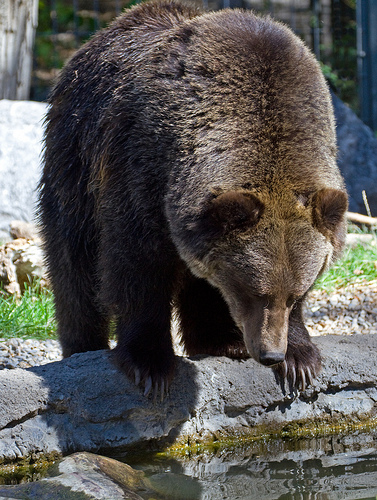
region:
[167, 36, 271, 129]
brown fur on a bear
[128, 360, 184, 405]
the claw of a bear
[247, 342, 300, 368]
the nose of a bear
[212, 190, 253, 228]
the ear of a bear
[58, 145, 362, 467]
a bear looking into the water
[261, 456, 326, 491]
reflection on the water's surface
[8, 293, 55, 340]
tall green grass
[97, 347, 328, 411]
a bear standing on rock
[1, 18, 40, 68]
the trunk of a tree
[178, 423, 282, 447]
moss on a rock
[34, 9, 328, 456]
Outdoor scene of a bear.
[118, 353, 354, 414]
The bear has long nails.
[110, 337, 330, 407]
The nails are brown.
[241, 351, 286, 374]
The bear's nose is black.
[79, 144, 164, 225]
The bear has brown fur.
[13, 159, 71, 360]
Picture taken during the day time.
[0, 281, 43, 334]
The grass is green.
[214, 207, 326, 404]
The bear is looking down at the water.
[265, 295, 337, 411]
The bear's left paw is off the rock.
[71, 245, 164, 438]
The bear's right front paw is on the rock.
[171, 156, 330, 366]
Grizzly Bears Fluffy Face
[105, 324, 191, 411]
Long grizzly bear claws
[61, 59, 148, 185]
Fluffy brown hair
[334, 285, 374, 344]
Rocks in the grass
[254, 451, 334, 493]
Clean drinking water for animals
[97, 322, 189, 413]
Dark colored long toe nails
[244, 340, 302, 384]
Black bear snout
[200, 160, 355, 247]
Two Grizzly Bear Ears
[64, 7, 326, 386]
Huge Grizzly bear in captivity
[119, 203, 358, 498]
Grizzly bear looking at reflection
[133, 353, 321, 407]
the bear has claws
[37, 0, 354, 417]
the bear is furry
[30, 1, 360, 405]
the bear is big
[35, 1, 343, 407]
the bear is brown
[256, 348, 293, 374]
the bear has a black nose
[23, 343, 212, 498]
the bear is casting a shadow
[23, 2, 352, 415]
the bear is looking at the water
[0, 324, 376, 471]
the bear is standing on the stones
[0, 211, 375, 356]
the grass is green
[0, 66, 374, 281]
the rock behind the bear is big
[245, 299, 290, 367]
Brown snout on the front of a bears face.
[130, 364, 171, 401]
Claws on a bears right paw.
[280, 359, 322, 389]
Long sharp claws on a bears left paw.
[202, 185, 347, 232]
Furry dark brown ears on a brown bear.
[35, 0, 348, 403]
Brown bear looking into the water.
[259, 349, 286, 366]
Black nose of a brown bear.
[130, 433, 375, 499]
Water down lower than the bear looking into it.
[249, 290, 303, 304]
Eyes of a brown bear.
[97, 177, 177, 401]
Right front arm of a brown bear.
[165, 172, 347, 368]
Head of a large brown bear.